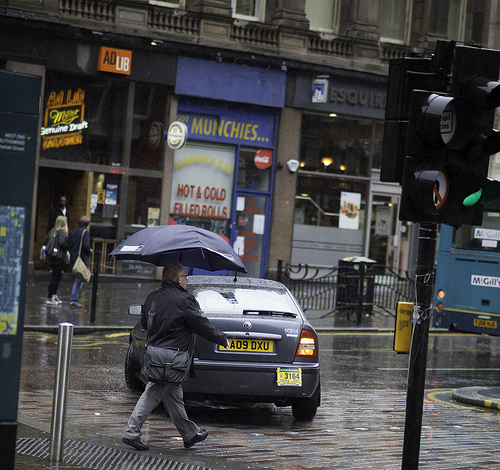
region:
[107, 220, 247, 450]
man holding an umbrella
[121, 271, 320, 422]
gray car with yellow license plate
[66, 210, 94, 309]
person carrying a brown satchel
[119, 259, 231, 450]
man with a gray satchel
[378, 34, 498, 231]
black traffic light fixtures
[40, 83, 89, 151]
neon orange sign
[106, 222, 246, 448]
man walking with black umbrella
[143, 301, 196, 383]
a man's black bag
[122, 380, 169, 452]
a man's right leg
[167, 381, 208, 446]
a man's left leg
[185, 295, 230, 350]
a man's right arm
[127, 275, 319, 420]
a small grey car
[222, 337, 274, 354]
a yellow and black license plate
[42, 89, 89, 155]
Miller beer sign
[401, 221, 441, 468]
a black metal pole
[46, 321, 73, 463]
shiny chrome metal pole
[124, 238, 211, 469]
This is a person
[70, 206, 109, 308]
This is a person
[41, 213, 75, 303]
This is a person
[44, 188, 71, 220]
This is a person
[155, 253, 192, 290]
Head of a person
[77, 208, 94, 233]
Head of a person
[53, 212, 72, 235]
Head of a person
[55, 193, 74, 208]
Head of a person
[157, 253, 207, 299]
Head of a person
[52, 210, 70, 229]
Head of a person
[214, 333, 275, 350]
The license plate of the car.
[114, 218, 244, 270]
The umbrella the man is holding.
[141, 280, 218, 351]
The black jacket the man is wearing.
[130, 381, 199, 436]
The gray pants the man is wearing.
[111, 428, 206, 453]
The black shoes the man is wearing.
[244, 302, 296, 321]
The windshield wiper on the back window of the car.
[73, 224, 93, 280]
The beige bag the person is carrying.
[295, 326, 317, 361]
The right brake light on the car.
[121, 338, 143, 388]
The front wheel of the car.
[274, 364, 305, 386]
The yellow sticker on the car.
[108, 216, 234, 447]
man holding an umbrella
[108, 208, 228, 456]
man wearnig black jacket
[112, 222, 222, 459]
man carrying black bag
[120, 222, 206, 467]
man wearing gray pants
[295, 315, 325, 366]
light on a car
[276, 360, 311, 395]
license plate on a car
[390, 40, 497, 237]
traffic light on a pole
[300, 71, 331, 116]
sign on a building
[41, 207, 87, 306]
people on a side walk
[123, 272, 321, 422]
the gray colored car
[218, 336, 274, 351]
the yellow license plate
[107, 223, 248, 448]
the man holding the umbrella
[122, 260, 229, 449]
the man carrying the bag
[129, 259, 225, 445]
a man walking in the rain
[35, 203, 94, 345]
two woman walking together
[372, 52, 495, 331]
a stop light that is black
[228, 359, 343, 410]
a yellow sing on the back of a car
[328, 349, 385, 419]
rain on the road way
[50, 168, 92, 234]
a man looking at the rain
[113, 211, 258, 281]
black colored umbrella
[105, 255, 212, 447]
man in black holding a black umbrella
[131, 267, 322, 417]
grey colored car on street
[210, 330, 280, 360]
yellow colored license plate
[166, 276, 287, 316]
back window of car